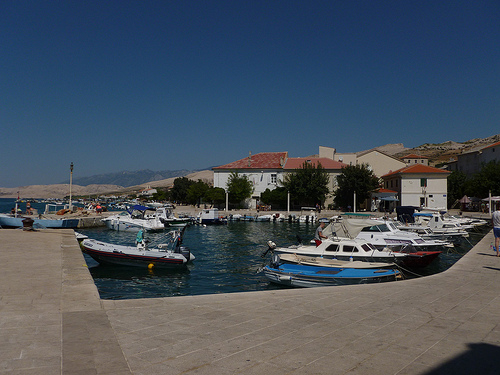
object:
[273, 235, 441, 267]
boat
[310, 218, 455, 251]
boat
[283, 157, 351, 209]
building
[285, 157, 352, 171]
roof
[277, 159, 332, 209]
tree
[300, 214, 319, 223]
boat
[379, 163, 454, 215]
building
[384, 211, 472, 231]
boat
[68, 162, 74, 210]
post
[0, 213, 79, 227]
boat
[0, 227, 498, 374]
floor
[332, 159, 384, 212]
tree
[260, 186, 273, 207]
tree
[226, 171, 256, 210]
tree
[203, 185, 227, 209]
tree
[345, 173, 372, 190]
leaves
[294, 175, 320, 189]
leaves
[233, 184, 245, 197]
leaves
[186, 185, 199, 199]
leaves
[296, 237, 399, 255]
top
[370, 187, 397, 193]
roof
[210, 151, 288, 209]
building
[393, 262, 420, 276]
rope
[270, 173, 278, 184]
window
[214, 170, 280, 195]
wall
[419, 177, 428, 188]
window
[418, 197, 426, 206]
window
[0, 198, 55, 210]
water surface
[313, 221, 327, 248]
guy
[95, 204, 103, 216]
person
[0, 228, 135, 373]
platform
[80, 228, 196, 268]
boat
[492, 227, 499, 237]
shorts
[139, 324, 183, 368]
part of a ground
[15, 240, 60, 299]
part of a floor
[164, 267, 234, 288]
part of a water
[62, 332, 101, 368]
part of floor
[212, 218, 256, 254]
part of  water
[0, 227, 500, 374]
tile deck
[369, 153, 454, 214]
several buildings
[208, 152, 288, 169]
red roof on building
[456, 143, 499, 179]
tree near building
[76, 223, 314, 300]
deep blue water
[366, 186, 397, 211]
building behind boat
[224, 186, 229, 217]
post behind boats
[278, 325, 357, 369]
of a floor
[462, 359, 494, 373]
part of a shade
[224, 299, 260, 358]
part of a floor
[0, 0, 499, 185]
blue of daytime sky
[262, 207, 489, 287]
row of docked boats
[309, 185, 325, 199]
green leaves on tree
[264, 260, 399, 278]
blue top of boat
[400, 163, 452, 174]
red roof of building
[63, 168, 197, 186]
hazy mountain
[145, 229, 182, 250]
rope on tip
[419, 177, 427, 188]
indow on white wall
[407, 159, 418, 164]
two windows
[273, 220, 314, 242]
reflection on water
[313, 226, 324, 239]
gray shirt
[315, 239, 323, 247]
red shorts